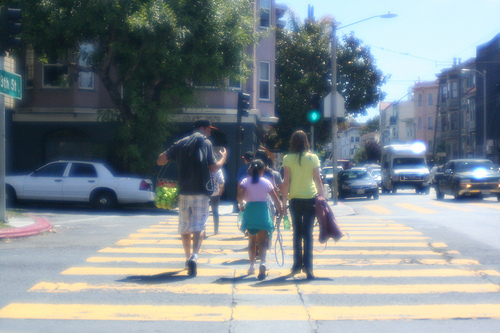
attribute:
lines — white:
[6, 211, 452, 316]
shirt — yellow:
[282, 150, 321, 200]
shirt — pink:
[235, 177, 273, 202]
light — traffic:
[305, 82, 324, 140]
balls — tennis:
[157, 187, 175, 209]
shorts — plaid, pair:
[173, 192, 213, 237]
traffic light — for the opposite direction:
[233, 88, 251, 172]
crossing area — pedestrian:
[76, 210, 440, 314]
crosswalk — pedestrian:
[358, 191, 498, 225]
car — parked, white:
[8, 157, 158, 213]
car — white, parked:
[10, 153, 159, 209]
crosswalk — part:
[0, 206, 498, 330]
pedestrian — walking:
[147, 102, 236, 282]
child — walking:
[225, 140, 289, 293]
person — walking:
[269, 119, 352, 285]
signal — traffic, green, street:
[293, 79, 332, 134]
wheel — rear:
[83, 183, 125, 223]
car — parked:
[2, 143, 168, 216]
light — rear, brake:
[131, 173, 160, 194]